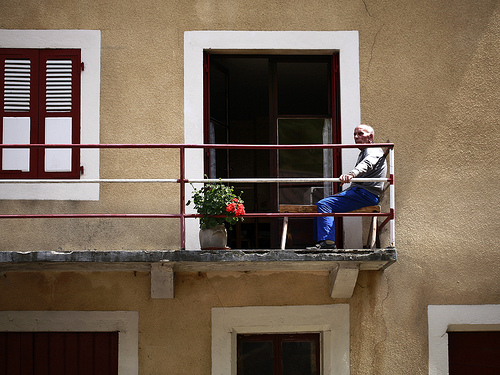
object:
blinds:
[1, 48, 86, 178]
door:
[203, 49, 342, 248]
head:
[354, 125, 375, 150]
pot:
[198, 223, 227, 250]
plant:
[185, 172, 248, 230]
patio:
[0, 130, 403, 300]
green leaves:
[185, 174, 226, 229]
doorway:
[182, 29, 363, 248]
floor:
[0, 249, 397, 273]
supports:
[146, 261, 359, 300]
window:
[0, 23, 104, 196]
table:
[0, 47, 86, 185]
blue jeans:
[314, 183, 382, 242]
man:
[306, 124, 388, 250]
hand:
[339, 174, 354, 186]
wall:
[0, 1, 499, 375]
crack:
[360, 0, 385, 77]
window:
[231, 328, 323, 375]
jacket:
[349, 146, 388, 198]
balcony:
[0, 139, 398, 299]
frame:
[1, 27, 102, 202]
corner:
[182, 30, 239, 73]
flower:
[226, 197, 246, 217]